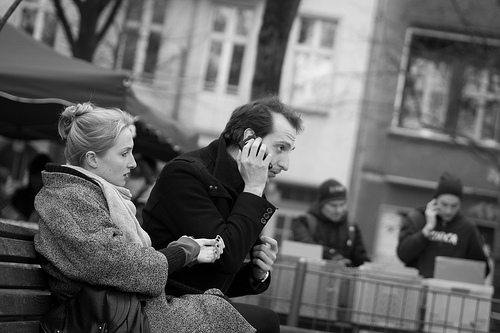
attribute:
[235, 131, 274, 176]
phone — black, mobile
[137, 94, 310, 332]
man — talking, sitting, caucasian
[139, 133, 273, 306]
jacket — black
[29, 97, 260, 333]
woman — sitting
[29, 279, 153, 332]
purse — black, large, leather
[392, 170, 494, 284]
man — standing, looking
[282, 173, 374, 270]
man — standing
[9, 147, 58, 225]
person — standing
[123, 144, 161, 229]
person — standing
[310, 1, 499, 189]
tree — bare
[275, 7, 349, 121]
window — blurred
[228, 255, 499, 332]
fence — metal, short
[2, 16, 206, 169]
awning — dark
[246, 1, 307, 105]
trunk — curved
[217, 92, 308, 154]
hair — receding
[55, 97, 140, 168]
hair — blonde, long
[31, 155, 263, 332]
clothing — elegant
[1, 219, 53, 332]
slats — wooden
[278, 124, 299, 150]
skin — wrinkled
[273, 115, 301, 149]
forehead — wrinkled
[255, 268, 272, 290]
watch — expensive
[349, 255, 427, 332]
bin — plastic